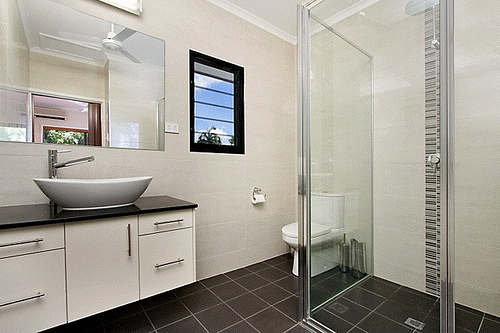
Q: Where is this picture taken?
A: A bathroom.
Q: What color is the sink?
A: White.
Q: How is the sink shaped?
A: As an oval.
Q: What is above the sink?
A: Mirror.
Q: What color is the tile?
A: Black.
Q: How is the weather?
A: Clear.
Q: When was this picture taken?
A: Daytime.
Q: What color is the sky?
A: Blue.